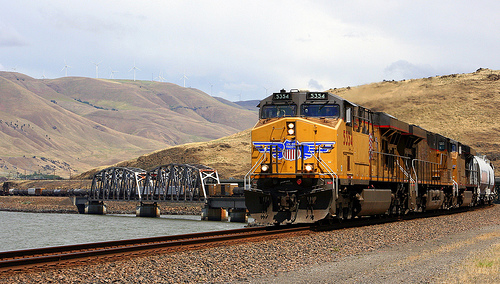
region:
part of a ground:
[371, 224, 408, 262]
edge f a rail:
[218, 223, 233, 239]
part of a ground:
[370, 234, 399, 266]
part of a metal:
[304, 171, 340, 238]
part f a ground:
[369, 220, 396, 244]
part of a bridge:
[176, 179, 204, 216]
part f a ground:
[368, 198, 415, 247]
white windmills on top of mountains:
[52, 55, 187, 82]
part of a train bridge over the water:
[92, 163, 212, 205]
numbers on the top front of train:
[271, 91, 327, 103]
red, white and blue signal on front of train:
[250, 138, 335, 159]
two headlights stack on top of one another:
[286, 120, 296, 136]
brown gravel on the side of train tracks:
[173, 250, 275, 276]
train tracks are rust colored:
[52, 237, 179, 261]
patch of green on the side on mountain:
[78, 95, 125, 115]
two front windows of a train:
[259, 99, 338, 124]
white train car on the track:
[472, 150, 498, 205]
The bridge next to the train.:
[88, 167, 215, 194]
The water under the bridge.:
[2, 208, 245, 235]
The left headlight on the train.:
[260, 163, 268, 170]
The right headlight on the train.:
[302, 160, 316, 171]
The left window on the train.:
[262, 103, 300, 119]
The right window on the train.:
[299, 103, 339, 113]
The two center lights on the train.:
[287, 119, 294, 135]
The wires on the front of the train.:
[250, 183, 331, 225]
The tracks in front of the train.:
[2, 223, 304, 250]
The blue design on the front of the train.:
[249, 133, 334, 161]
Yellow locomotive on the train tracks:
[229, 78, 479, 245]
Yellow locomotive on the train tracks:
[246, 85, 480, 240]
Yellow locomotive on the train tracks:
[241, 78, 478, 235]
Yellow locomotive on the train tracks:
[231, 65, 476, 254]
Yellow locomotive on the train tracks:
[252, 88, 483, 251]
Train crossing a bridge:
[81, 168, 246, 211]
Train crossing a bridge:
[138, 163, 244, 200]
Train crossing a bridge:
[91, 170, 221, 196]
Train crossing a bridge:
[79, 172, 254, 193]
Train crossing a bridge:
[87, 177, 244, 202]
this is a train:
[248, 90, 498, 226]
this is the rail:
[1, 222, 323, 274]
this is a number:
[307, 87, 330, 99]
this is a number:
[272, 89, 293, 102]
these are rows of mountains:
[1, 69, 247, 131]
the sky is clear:
[11, 7, 90, 72]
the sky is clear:
[97, 3, 198, 66]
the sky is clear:
[326, 12, 382, 82]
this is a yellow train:
[251, 84, 494, 214]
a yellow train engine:
[246, 88, 475, 228]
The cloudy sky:
[3, 5, 498, 92]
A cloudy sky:
[3, 1, 498, 87]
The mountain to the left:
[1, 60, 268, 191]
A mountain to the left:
[1, 66, 261, 186]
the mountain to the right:
[317, 55, 495, 182]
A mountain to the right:
[314, 75, 493, 151]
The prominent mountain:
[106, 112, 252, 206]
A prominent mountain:
[103, 117, 255, 192]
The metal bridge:
[87, 157, 209, 213]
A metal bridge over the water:
[81, 151, 223, 208]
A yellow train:
[136, 86, 424, 236]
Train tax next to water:
[98, 146, 255, 251]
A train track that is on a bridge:
[56, 99, 243, 233]